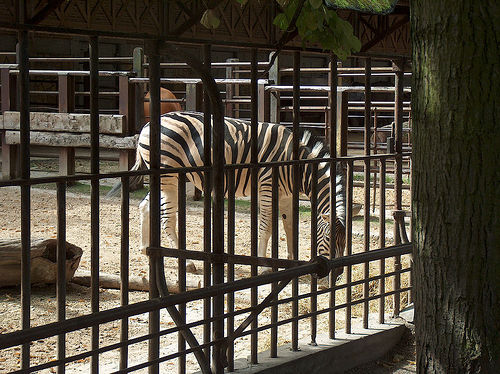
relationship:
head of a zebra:
[311, 201, 362, 276] [104, 111, 359, 273]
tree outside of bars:
[402, 5, 498, 372] [0, 0, 419, 374]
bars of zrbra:
[118, 66, 390, 323] [106, 105, 367, 277]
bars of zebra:
[0, 0, 419, 374] [123, 115, 358, 277]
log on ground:
[1, 233, 87, 298] [1, 148, 408, 370]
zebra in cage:
[103, 111, 362, 284] [10, 45, 423, 371]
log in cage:
[1, 233, 87, 298] [10, 45, 423, 371]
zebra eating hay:
[103, 111, 362, 284] [289, 231, 430, 321]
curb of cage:
[301, 325, 398, 371] [10, 45, 423, 371]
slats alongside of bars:
[0, 109, 145, 150] [0, 0, 419, 374]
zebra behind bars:
[103, 111, 362, 284] [8, 5, 420, 372]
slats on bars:
[2, 104, 151, 154] [0, 0, 419, 374]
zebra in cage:
[115, 104, 368, 285] [10, 45, 423, 371]